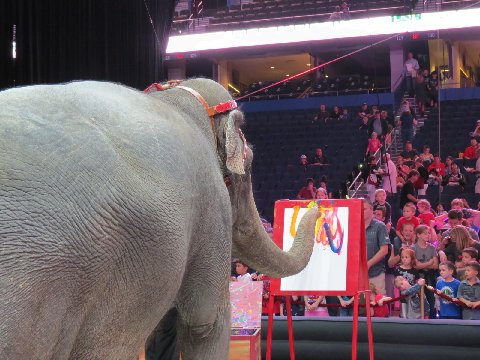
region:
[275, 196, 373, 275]
red easel board with stands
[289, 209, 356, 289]
white paper on easel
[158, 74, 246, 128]
red harness on elephant's head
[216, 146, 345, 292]
gray elephant's long tusk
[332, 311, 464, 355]
long gray barrier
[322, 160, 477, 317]
spectators in stand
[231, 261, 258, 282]
little boy watching activities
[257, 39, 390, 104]
long pink overhead wire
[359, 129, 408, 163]
woman wearing pink shirt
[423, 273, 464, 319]
boy wearing blue shirt with white peace symbol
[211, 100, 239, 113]
Red halter strap on elephant head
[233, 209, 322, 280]
Long gray elephant trunk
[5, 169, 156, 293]
Wrinkled gray skin on elephant rear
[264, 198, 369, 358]
Red painting easel on stage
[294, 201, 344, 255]
Yellow red and blue paint swirls on paper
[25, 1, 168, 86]
Dark brown stage curtan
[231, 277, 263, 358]
Wooden box of paints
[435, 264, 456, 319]
Boy in blue shirt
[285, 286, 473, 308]
Red velvet rope across stage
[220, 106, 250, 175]
Gray fuzzy elephant ear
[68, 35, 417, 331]
grey circus elephant performing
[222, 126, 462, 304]
crowd of adults and children at circus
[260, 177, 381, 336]
elephant using trunk to paint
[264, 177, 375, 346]
red easel holding white sheet of paper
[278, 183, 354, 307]
elephant artwork of loops in different colors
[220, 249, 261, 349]
person behind box with a lid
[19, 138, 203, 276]
wrinkles on the back of the elephant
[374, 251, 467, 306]
children holding velvet rope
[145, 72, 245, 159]
decorated harness on elephant's head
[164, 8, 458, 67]
bank of bright light across arena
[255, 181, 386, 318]
elephant trunk drawing a picture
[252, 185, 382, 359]
a pink easel with white paper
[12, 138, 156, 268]
rough texture of an elephant's skin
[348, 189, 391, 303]
a man standing in a green shirt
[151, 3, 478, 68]
rectangular stage lights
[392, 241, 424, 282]
a red haired girl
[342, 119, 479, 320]
a crowd with many children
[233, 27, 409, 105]
a pink rope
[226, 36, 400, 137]
a balcony above the main floor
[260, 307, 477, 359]
a rail separating the audience from the act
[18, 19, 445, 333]
elephant painting picture for crowd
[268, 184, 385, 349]
red easel holding painting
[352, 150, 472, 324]
children watching elephant paint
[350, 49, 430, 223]
people climbing up and down the stairs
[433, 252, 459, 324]
boy wearing blue shirt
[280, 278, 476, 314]
red velvet rope barrier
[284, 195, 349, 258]
blue, red, and yellow paint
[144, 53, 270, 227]
elephant wearing red harness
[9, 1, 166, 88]
black curtains in background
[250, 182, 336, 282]
elephants trunk holding brush